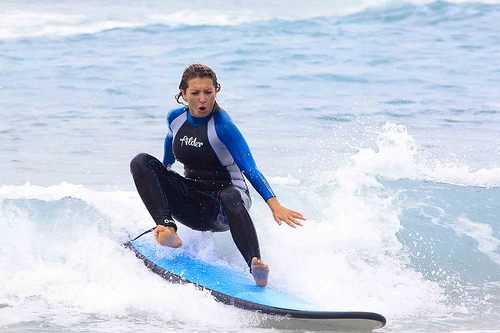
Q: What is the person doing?
A: Surfing.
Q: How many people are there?
A: One.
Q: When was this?
A: Daytime.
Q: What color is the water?
A: Blue.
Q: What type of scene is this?
A: Outdoor.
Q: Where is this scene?
A: Waterbody.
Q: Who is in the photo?
A: A surfer.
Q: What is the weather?
A: Sunny.